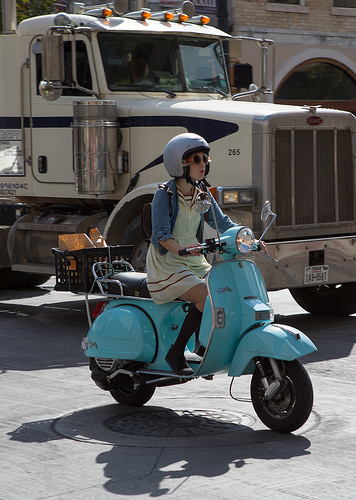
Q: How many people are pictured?
A: One.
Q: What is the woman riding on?
A: A scooter.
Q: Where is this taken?
A: A street.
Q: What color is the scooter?
A: Blue.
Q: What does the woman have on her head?
A: A helmet.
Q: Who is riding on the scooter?
A: A woman.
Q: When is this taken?
A: Daytime.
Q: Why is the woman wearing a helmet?
A: To protect her head.